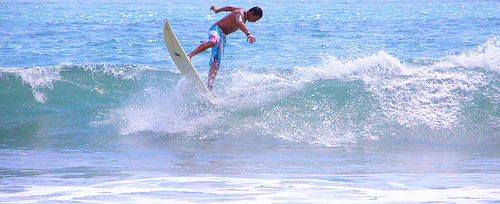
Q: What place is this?
A: It is an ocean.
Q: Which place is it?
A: It is an ocean.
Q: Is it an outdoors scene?
A: Yes, it is outdoors.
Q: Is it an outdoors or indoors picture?
A: It is outdoors.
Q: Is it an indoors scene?
A: No, it is outdoors.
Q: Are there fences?
A: No, there are no fences.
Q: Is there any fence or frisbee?
A: No, there are no fences or frisbees.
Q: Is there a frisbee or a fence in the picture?
A: No, there are no fences or frisbees.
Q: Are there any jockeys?
A: No, there are no jockeys.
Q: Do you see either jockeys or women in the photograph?
A: No, there are no jockeys or women.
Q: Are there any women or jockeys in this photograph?
A: No, there are no jockeys or women.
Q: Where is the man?
A: The man is in the ocean.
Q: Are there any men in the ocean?
A: Yes, there is a man in the ocean.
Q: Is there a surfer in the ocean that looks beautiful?
A: No, there is a man in the ocean.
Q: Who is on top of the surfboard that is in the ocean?
A: The man is on top of the surfboard.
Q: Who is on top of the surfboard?
A: The man is on top of the surfboard.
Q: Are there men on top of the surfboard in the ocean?
A: Yes, there is a man on top of the surfboard.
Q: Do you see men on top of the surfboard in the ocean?
A: Yes, there is a man on top of the surfboard.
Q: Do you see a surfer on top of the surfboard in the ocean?
A: No, there is a man on top of the surf board.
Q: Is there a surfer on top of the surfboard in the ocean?
A: No, there is a man on top of the surf board.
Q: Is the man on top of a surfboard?
A: Yes, the man is on top of a surfboard.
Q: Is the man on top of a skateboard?
A: No, the man is on top of a surfboard.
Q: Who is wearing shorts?
A: The man is wearing shorts.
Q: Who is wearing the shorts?
A: The man is wearing shorts.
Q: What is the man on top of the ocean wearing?
A: The man is wearing shorts.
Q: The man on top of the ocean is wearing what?
A: The man is wearing shorts.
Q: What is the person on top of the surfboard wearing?
A: The man is wearing shorts.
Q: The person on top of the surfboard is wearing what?
A: The man is wearing shorts.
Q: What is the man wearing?
A: The man is wearing shorts.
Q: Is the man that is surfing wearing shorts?
A: Yes, the man is wearing shorts.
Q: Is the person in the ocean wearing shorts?
A: Yes, the man is wearing shorts.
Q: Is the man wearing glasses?
A: No, the man is wearing shorts.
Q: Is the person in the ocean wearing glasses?
A: No, the man is wearing shorts.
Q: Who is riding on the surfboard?
A: The man is riding on the surfboard.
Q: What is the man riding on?
A: The man is riding on the surfboard.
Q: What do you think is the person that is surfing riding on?
A: The man is riding on the surfboard.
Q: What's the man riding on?
A: The man is riding on the surfboard.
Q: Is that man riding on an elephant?
A: No, the man is riding on the surf board.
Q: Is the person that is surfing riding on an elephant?
A: No, the man is riding on the surf board.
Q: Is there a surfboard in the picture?
A: Yes, there is a surfboard.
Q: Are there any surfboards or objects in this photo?
A: Yes, there is a surfboard.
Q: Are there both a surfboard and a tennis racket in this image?
A: No, there is a surfboard but no rackets.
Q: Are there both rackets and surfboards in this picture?
A: No, there is a surfboard but no rackets.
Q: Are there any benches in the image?
A: No, there are no benches.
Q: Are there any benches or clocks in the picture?
A: No, there are no benches or clocks.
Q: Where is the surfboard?
A: The surfboard is in the ocean.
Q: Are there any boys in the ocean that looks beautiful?
A: No, there is a surfboard in the ocean.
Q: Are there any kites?
A: No, there are no kites.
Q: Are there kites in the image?
A: No, there are no kites.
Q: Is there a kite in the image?
A: No, there are no kites.